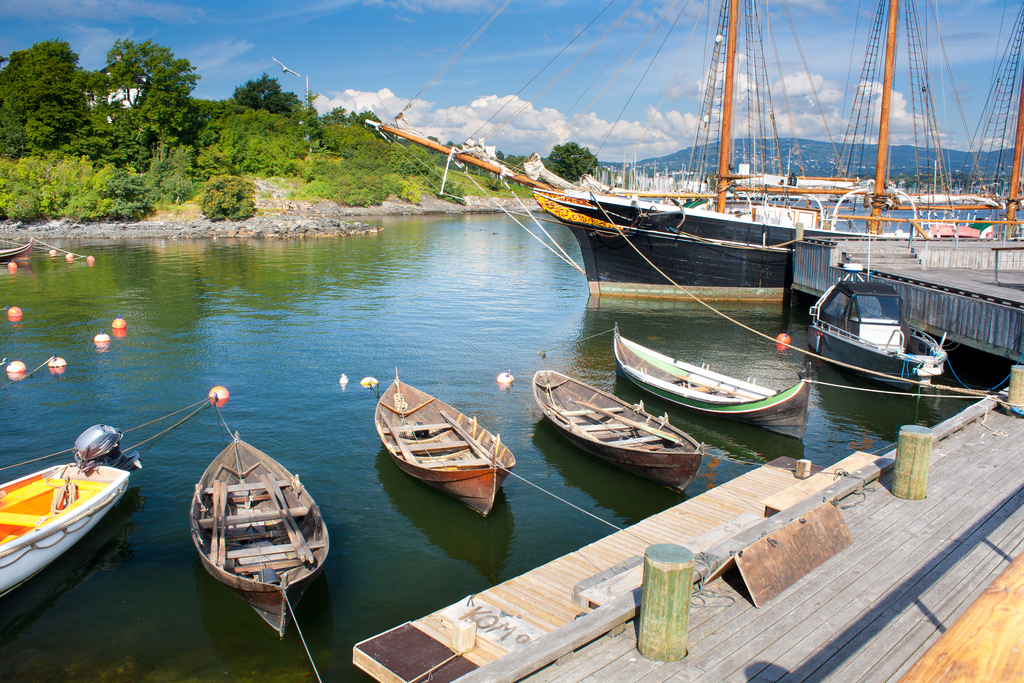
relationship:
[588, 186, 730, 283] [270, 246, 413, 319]
boat in water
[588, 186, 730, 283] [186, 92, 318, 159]
boat near land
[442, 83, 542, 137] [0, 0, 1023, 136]
clouds in blue sky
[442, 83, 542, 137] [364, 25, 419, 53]
clouds in blue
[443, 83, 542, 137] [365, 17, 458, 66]
clouds in blue sky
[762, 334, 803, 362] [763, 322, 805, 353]
orange and white floating balls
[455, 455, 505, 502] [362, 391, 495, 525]
red and brown canoe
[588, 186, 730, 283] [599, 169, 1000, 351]
ship at dock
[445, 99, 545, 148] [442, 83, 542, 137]
fluffy white clouds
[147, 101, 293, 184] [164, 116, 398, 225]
bushes and trees on hill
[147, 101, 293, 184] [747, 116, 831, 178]
mountain range in distance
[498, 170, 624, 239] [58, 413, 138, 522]
yellow orange and white boat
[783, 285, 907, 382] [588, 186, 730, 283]
small blue and white boat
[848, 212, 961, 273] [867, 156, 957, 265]
short wooden post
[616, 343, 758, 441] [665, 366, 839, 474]
green and white canoe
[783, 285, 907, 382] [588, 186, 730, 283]
small yellow boat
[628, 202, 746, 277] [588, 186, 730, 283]
large black boat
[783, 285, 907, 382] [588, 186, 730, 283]
small green boat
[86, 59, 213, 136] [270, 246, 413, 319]
trees behind water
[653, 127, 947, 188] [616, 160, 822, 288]
mountain behind boats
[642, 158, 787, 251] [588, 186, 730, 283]
wires on boat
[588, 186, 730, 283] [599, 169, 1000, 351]
boat tied to dock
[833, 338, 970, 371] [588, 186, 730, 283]
motor on boat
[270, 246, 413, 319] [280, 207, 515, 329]
water covering surface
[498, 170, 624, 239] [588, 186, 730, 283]
yellow coloring boat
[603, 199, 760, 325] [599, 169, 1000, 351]
rope on dock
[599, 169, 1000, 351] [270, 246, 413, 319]
dock in water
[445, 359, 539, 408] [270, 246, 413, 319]
bouys in water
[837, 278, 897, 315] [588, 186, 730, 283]
window on boat